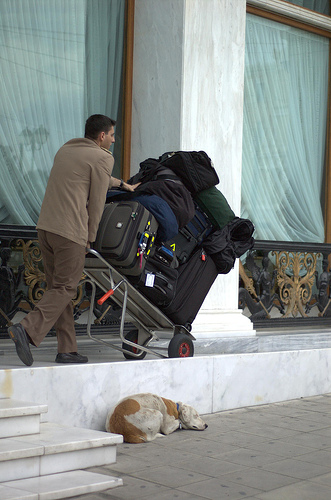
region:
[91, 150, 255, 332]
A pile of luggage.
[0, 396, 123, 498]
A set of marbled steps.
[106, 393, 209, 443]
Brown and white dog.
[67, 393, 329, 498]
Tiled gray walk way.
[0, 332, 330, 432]
A marbled walking area.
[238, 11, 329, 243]
A long white curtain.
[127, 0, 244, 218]
A large marble pillar.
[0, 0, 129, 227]
A large covered window.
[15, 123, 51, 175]
A reflection of lamps.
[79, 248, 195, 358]
A metal luggage cart.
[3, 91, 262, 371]
man pushing roller cart filled with suitcases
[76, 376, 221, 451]
white and brown dog sleeping on pavement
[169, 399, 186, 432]
blue collar on dog neck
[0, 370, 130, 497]
three white steps on sidewalk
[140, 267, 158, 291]
white luggage tag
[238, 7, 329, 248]
white curtain covering store front window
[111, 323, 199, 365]
two red and black wheels on bottom of luggage rack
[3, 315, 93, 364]
black flat shoes on man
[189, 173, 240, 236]
square bottom of green piece of luggage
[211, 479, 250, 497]
grey stains on sidewalk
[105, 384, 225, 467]
the dog is sleeping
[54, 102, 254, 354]
a cart of luggages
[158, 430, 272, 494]
a small brick sidewalk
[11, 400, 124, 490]
a set of marble stairs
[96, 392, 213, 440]
a dog sleeping on the street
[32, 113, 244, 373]
a man pushing a luggage cart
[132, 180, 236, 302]
a bunch of black luggage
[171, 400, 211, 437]
the head of a sleeping dog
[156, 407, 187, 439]
the paw of a sleeping dog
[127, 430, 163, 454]
the tail of a sleeping dog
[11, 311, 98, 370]
the shoes of an adult male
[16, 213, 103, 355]
a pair of brown pants